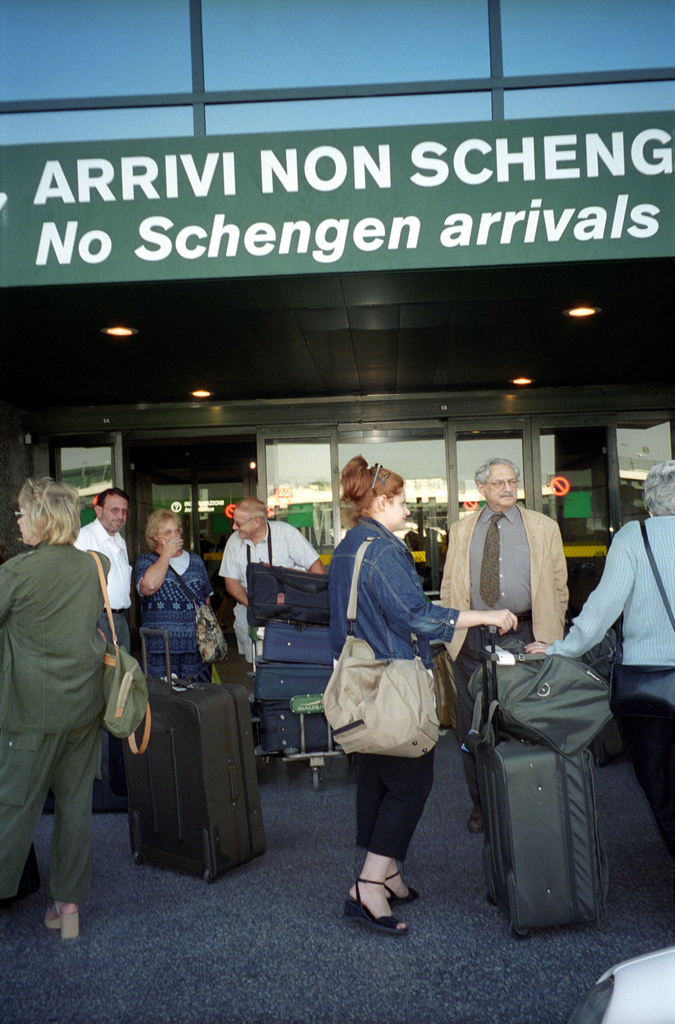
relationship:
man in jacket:
[439, 458, 570, 828] [442, 506, 570, 660]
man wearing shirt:
[74, 485, 132, 799] [73, 516, 134, 612]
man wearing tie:
[433, 459, 575, 639] [473, 506, 524, 606]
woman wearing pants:
[0, 473, 108, 936] [12, 708, 93, 909]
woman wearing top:
[0, 473, 108, 936] [2, 532, 117, 727]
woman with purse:
[523, 468, 675, 863] [601, 513, 652, 744]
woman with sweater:
[523, 468, 675, 863] [542, 514, 653, 667]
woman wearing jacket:
[322, 455, 519, 932] [315, 510, 469, 686]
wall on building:
[6, 366, 46, 487] [4, 7, 653, 794]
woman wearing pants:
[322, 455, 519, 932] [336, 752, 442, 852]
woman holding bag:
[322, 456, 526, 934] [326, 533, 441, 761]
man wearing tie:
[439, 458, 570, 828] [481, 509, 505, 607]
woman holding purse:
[515, 468, 653, 776] [605, 660, 652, 725]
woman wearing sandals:
[322, 456, 526, 934] [346, 871, 420, 936]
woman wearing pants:
[0, 473, 108, 936] [7, 711, 105, 904]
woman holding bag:
[0, 473, 108, 936] [87, 547, 154, 748]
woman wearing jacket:
[0, 473, 108, 936] [6, 536, 115, 727]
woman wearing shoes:
[9, 473, 108, 934] [43, 903, 85, 942]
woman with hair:
[322, 456, 526, 934] [333, 450, 387, 510]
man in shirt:
[74, 481, 132, 785] [79, 514, 139, 610]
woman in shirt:
[141, 508, 219, 674] [142, 551, 209, 651]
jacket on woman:
[325, 516, 471, 686] [322, 456, 526, 934]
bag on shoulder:
[317, 530, 440, 771] [336, 525, 414, 607]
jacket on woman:
[550, 522, 651, 674] [530, 465, 650, 786]